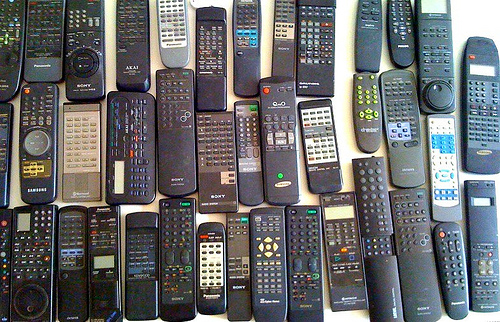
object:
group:
[65, 46, 420, 280]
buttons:
[364, 114, 374, 120]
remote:
[352, 72, 382, 155]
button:
[262, 86, 270, 94]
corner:
[262, 87, 270, 94]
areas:
[431, 188, 457, 201]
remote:
[272, 0, 297, 79]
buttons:
[129, 149, 134, 158]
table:
[336, 1, 499, 196]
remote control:
[232, 0, 262, 99]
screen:
[324, 204, 355, 220]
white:
[304, 110, 334, 125]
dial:
[423, 80, 454, 110]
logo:
[209, 193, 226, 198]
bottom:
[198, 190, 239, 214]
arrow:
[257, 242, 265, 253]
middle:
[254, 235, 283, 258]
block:
[435, 188, 458, 201]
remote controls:
[195, 221, 228, 315]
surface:
[267, 0, 490, 116]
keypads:
[124, 98, 150, 198]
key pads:
[431, 119, 459, 201]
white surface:
[429, 118, 454, 135]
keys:
[363, 107, 374, 114]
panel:
[160, 8, 185, 43]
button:
[23, 130, 50, 157]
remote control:
[105, 91, 158, 206]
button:
[276, 171, 284, 179]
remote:
[155, 0, 190, 68]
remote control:
[352, 156, 394, 240]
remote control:
[158, 198, 198, 321]